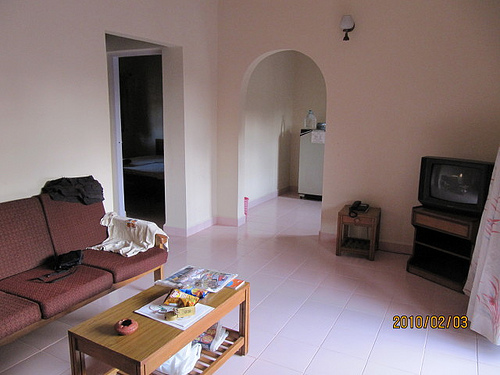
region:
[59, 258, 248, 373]
Wooden coffee table.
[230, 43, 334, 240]
Domed archway in the wall.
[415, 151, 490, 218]
Black television on the stand.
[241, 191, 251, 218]
Pink wastebasket in the background.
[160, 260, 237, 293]
Newspaper on the table.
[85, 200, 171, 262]
White shirt on the arm of the couch.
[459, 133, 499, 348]
White drapes with red design.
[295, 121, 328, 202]
Refrigerator in the background.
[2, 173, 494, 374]
White tile covering the floor.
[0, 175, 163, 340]
Maroon couch cushions.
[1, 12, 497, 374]
living room of dwelling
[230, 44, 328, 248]
Arch entry into the kitchen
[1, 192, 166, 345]
Marron couch next to the wall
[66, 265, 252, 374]
Wood coffee table in the living area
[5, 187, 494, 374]
tile floor covering in the home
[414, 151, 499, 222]
Black TV on stand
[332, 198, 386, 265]
Small table with a telephone on it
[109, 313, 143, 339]
Ashtray on top of the table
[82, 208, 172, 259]
White T-shirt on the couch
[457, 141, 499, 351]
White curtains with pink on the right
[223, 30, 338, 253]
THIS IS AN ARCHWAY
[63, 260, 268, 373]
THIS IS A COFFEE TABLE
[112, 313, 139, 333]
THIS IS AN ASHTRAY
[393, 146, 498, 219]
THIS IS A TELEVISION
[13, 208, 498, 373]
THE FLOOR IS WHITE TILE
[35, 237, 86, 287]
THE PURSE IS ON THE COUCH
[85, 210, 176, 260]
THE SHIRT IS ON THE COUCH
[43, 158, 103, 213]
THE PANTS ARE ON THE COUCH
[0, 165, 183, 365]
THE COUCH LOOKS CHEAP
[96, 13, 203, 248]
THE DOOR IS BIG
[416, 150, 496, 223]
A TV is sitting on a stand.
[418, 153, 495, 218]
The colors of a TV are black and gray.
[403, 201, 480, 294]
The colors of a stand are brown and black.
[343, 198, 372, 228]
A phone is sitting on a small piece of furniture.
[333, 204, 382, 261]
A small piece of furniture is next to a wall.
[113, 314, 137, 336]
A pink object is sitting on a table.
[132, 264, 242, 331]
Several objects are sitting on a coffee table.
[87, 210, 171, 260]
A shirt is laying on the arm of a sofa.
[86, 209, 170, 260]
The color of a shirt is white and red.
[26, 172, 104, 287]
Two black objects are laying on a sofa.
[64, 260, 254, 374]
Coffee table in front of the couch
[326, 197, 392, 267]
The small table next to the tv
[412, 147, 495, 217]
The tv in the corner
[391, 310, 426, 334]
The year the photo was taken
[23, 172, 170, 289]
The clothes on the couch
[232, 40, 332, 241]
The arched doorway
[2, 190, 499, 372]
The tile covered ground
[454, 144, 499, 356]
The floral print curtain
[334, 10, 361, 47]
The light hanging on the wall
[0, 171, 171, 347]
The couch next to the coffee table